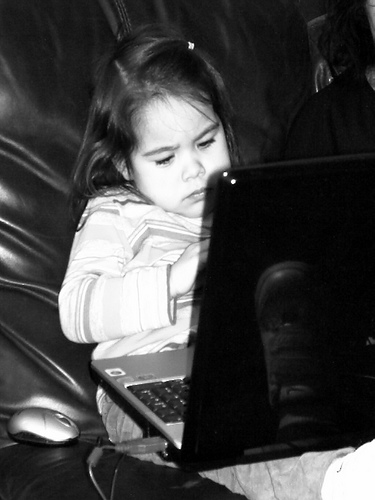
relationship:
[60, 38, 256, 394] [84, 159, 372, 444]
girl has computer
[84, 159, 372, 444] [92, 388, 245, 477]
computer on top of girls lap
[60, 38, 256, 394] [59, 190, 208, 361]
girl wearing shirt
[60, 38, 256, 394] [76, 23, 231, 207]
girl has hair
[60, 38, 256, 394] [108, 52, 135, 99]
girl has part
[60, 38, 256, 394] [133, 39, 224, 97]
girl has a side ponytail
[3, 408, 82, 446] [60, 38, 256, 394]
mouse sitting next to girl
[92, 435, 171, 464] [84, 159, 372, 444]
plug plugged into computer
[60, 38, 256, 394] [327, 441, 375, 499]
girl wearing shoe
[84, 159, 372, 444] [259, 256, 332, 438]
computer has reflection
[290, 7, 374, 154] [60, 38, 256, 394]
person sitting next to girl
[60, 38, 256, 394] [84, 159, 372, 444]
girl looking at computer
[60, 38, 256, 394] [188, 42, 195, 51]
girl wearing a band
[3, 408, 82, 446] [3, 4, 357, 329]
mouse sitting on top of couch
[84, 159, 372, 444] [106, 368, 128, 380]
computer has a logo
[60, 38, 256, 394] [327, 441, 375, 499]
girl wearing a white sock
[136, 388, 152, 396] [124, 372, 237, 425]
key are on top of keyboard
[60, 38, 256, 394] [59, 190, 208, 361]
girl wearing a striped shirt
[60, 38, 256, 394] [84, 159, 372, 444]
girl playing with laptop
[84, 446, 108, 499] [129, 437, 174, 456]
usb cord plugged into laptop port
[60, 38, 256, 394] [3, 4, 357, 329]
girl sitting on couch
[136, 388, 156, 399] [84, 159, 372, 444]
key on top laptop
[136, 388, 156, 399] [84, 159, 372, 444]
key on laptop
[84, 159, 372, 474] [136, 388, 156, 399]
computer has a key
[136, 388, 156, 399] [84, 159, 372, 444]
key on top of a laptop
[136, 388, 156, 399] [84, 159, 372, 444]
key on top of laptop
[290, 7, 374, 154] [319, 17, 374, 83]
lady has hair